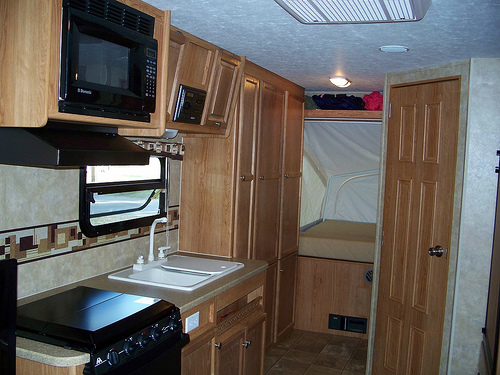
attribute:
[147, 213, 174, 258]
faucet — white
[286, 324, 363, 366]
tile — brown  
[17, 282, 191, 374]
range — black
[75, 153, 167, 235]
window — small, open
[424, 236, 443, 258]
doorknob — silver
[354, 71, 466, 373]
door — brown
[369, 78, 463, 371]
closed door — brown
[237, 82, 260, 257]
closed door — brown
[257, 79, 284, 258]
closed door — brown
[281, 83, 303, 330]
closed door — brown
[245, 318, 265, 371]
closed door — brown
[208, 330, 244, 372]
closed door — brown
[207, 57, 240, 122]
closed door — brown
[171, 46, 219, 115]
closed door — brown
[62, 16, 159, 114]
microwave — black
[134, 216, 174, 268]
faucet — white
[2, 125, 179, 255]
wall — grey, brown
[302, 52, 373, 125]
light — white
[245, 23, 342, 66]
ceiling — top 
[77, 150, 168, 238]
frame — black 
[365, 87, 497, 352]
door — brown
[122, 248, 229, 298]
sink — white 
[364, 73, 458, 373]
door — brown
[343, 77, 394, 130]
bag — pink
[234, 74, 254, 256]
cabinet — brown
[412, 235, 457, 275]
knob — silver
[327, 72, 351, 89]
light — small, on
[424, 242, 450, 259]
handle — nickel 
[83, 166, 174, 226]
cover — black 